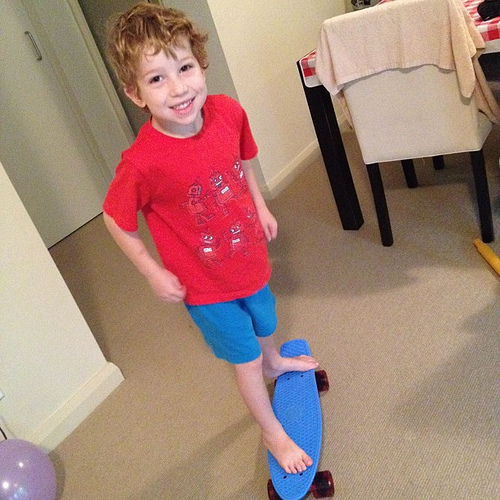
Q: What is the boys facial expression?
A: Happy.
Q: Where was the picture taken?
A: Inside the house.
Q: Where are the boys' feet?
A: On the skateboard.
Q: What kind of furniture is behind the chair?
A: The table.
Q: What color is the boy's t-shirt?
A: Red.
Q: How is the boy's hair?
A: Messy.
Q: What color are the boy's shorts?
A: Blue.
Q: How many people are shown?
A: 1.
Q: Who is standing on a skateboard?
A: Boy.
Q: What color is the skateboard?
A: Blue.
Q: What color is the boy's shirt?
A: Red.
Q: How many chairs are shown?
A: 1.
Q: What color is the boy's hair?
A: Red.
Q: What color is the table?
A: Black.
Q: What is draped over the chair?
A: Towel.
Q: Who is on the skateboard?
A: Boy.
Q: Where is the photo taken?
A: Living room.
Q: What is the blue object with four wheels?
A: Skateboard.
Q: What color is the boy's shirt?
A: Red.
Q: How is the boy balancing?
A: Feet.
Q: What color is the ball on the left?
A: Purple.